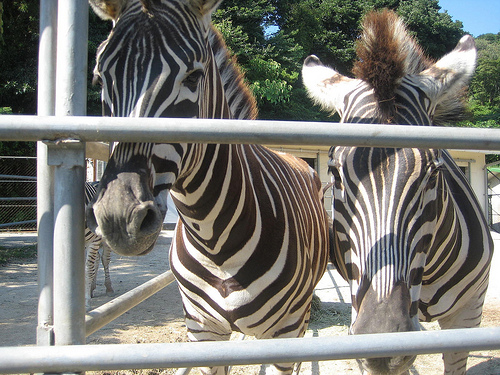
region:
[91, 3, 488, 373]
two zebras standing by a fence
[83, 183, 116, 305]
a zebra in the background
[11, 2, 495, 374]
a gray metal fence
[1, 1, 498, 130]
green trees in the background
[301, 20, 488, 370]
the zebra on the right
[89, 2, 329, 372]
zebra on the left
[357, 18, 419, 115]
the zebra on the right's mane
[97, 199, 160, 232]
the left zebra's nostrils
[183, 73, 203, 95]
left zebra's left eye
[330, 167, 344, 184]
right zebra's right eye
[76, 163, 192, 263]
nose of the zebra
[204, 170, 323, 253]
black and white animal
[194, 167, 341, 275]
black stripes on animal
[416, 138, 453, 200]
eye of the zebra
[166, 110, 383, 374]
silver poles in front of zebra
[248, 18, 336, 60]
trees in the distance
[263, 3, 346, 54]
green leaves on tree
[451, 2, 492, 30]
blue sky behind trees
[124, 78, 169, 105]
light on zebra's head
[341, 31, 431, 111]
hair on the zebra's head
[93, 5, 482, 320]
two zebras in the pen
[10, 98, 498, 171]
metal bar of the pen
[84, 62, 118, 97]
the eye of the zebra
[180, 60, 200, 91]
the eye of the zebra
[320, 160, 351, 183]
the eye of the zebra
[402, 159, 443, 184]
the eye of the zebra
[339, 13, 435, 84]
mane of the zebra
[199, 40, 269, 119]
mane of the zebra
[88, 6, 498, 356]
the zebras are striped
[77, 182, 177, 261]
nostrils of the zebra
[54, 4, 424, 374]
two zebras in a pen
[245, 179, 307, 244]
patterned fur coat of a zebra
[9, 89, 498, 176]
a metal pole of a fence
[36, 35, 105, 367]
metal enclosure of a pen for zebras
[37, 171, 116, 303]
another zebra in the background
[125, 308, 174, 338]
dirt ground of a zebra enclosure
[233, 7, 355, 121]
trees in the background of a zoo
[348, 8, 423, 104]
fluffy maine of a zebra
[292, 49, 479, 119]
zebra's ears perked up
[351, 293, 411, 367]
snout on a zebra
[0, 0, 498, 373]
a metal zoo fence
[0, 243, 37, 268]
a patch of green grass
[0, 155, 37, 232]
a metal fence in the background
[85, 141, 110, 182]
a building in the background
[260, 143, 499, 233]
a building in the background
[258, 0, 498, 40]
an area of blue sky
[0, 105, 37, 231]
green bushes in the background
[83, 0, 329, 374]
a zebra at the zoo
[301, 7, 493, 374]
a zebra at the zoo